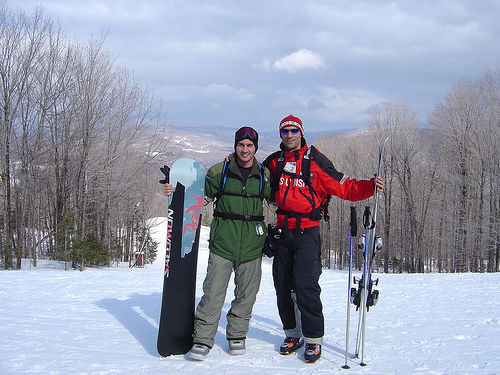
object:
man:
[223, 114, 386, 361]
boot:
[225, 337, 247, 355]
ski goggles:
[234, 126, 256, 139]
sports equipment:
[344, 205, 359, 367]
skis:
[354, 135, 391, 354]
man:
[164, 126, 279, 360]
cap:
[278, 114, 305, 133]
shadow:
[91, 288, 162, 356]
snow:
[0, 216, 499, 373]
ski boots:
[303, 342, 321, 363]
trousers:
[191, 251, 260, 346]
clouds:
[272, 49, 326, 72]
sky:
[0, 0, 499, 134]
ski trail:
[0, 309, 111, 322]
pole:
[344, 237, 352, 365]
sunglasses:
[279, 127, 304, 134]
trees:
[418, 69, 499, 271]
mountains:
[128, 127, 266, 217]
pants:
[271, 224, 324, 343]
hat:
[233, 125, 258, 149]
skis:
[358, 206, 370, 367]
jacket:
[262, 137, 374, 228]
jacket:
[203, 152, 274, 263]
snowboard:
[155, 157, 205, 357]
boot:
[184, 341, 209, 361]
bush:
[68, 232, 109, 268]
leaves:
[91, 243, 100, 250]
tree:
[358, 103, 416, 270]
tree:
[0, 0, 63, 268]